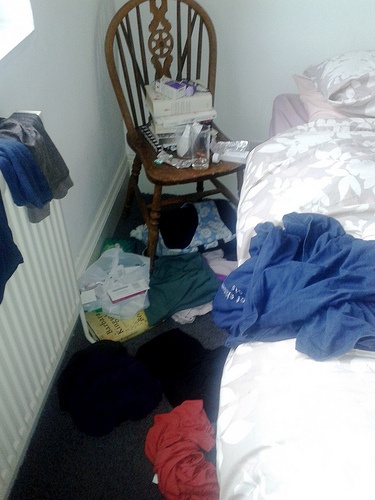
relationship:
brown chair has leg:
[103, 0, 246, 276] [148, 180, 162, 274]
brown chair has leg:
[103, 0, 246, 276] [123, 154, 137, 225]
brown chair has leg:
[103, 0, 246, 276] [194, 179, 209, 206]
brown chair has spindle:
[103, 0, 246, 276] [177, 0, 181, 80]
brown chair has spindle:
[103, 0, 246, 276] [133, 4, 147, 81]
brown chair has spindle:
[103, 0, 246, 276] [177, 32, 205, 70]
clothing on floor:
[129, 199, 236, 324] [8, 188, 238, 498]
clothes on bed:
[217, 211, 374, 350] [222, 59, 373, 496]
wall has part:
[0, 0, 374, 267] [62, 265, 79, 294]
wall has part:
[1, 0, 374, 267] [17, 212, 38, 244]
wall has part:
[0, 0, 374, 267] [9, 326, 65, 404]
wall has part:
[0, 0, 374, 267] [2, 413, 24, 456]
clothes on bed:
[211, 211, 375, 362] [258, 39, 374, 349]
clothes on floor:
[144, 398, 220, 500] [65, 333, 219, 495]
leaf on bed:
[331, 143, 344, 162] [222, 59, 373, 496]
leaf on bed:
[316, 147, 327, 171] [222, 59, 373, 496]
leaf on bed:
[308, 158, 333, 171] [222, 59, 373, 496]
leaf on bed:
[334, 173, 364, 206] [222, 59, 373, 496]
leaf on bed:
[313, 192, 332, 210] [222, 59, 373, 496]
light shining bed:
[247, 360, 359, 457] [218, 126, 370, 498]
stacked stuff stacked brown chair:
[141, 77, 250, 170] [103, 0, 246, 276]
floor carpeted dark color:
[8, 188, 238, 498] [18, 164, 206, 498]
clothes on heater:
[60, 317, 217, 482] [4, 112, 80, 496]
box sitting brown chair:
[152, 75, 188, 102] [103, 0, 246, 276]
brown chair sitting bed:
[103, 0, 246, 276] [261, 77, 374, 307]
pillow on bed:
[289, 42, 373, 127] [212, 84, 373, 497]